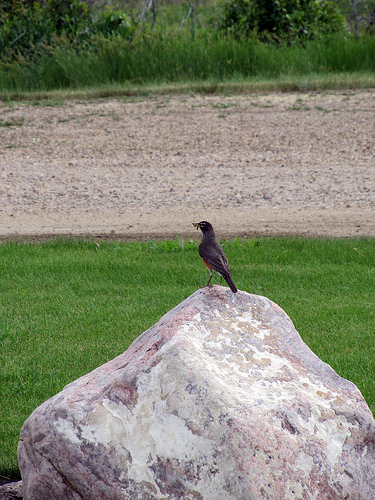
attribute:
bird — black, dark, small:
[190, 219, 238, 294]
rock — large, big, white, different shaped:
[14, 284, 374, 500]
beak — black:
[190, 221, 200, 229]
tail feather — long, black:
[224, 273, 238, 294]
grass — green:
[2, 237, 373, 479]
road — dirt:
[1, 89, 374, 237]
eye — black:
[199, 222, 206, 227]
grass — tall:
[0, 32, 373, 96]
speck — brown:
[240, 347, 272, 371]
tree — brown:
[344, 1, 374, 38]